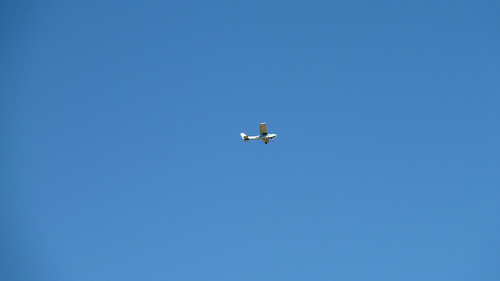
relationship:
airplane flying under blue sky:
[240, 122, 278, 144] [209, 39, 316, 90]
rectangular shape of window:
[261, 133, 268, 138] [263, 131, 268, 138]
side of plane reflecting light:
[243, 129, 263, 140] [241, 133, 273, 144]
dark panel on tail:
[243, 136, 251, 143] [241, 134, 250, 140]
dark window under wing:
[243, 136, 251, 143] [261, 129, 269, 138]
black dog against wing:
[240, 135, 253, 143] [250, 124, 270, 146]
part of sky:
[231, 29, 310, 69] [209, 39, 316, 90]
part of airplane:
[239, 131, 260, 142] [240, 122, 278, 144]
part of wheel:
[239, 131, 260, 142] [259, 134, 273, 146]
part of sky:
[231, 29, 310, 69] [243, 24, 303, 102]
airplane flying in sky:
[240, 122, 278, 144] [217, 32, 284, 108]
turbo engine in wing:
[257, 127, 272, 143] [257, 121, 270, 136]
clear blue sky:
[252, 38, 393, 118] [243, 24, 303, 102]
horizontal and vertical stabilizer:
[236, 121, 294, 153] [239, 129, 247, 139]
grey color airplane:
[232, 126, 285, 146] [240, 122, 278, 144]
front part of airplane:
[261, 126, 280, 144] [240, 122, 278, 144]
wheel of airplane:
[259, 134, 273, 146] [240, 122, 278, 144]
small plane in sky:
[243, 112, 290, 163] [217, 32, 284, 108]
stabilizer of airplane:
[239, 132, 246, 139] [236, 121, 294, 153]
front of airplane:
[267, 133, 279, 142] [225, 114, 286, 157]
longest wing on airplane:
[257, 121, 270, 136] [225, 114, 286, 157]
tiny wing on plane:
[262, 138, 270, 144] [260, 138, 272, 148]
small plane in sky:
[225, 114, 286, 157] [243, 24, 303, 102]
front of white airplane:
[267, 133, 279, 142] [240, 122, 278, 144]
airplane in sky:
[225, 114, 286, 157] [243, 24, 303, 102]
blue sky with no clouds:
[209, 39, 316, 90] [153, 26, 390, 108]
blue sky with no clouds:
[209, 39, 316, 90] [219, 13, 350, 99]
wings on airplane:
[257, 120, 276, 146] [232, 125, 278, 148]